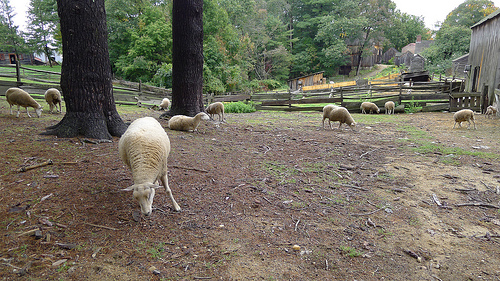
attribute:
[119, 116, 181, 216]
sheep — big, eating, white, sniffing, grazing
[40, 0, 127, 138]
tree — for shade, rough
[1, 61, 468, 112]
fence — wooden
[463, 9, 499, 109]
barn — wooden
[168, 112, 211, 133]
sheep — resting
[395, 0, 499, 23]
sky — blue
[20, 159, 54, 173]
stick — gray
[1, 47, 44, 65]
house — dilapidated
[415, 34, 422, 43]
chimney — brick